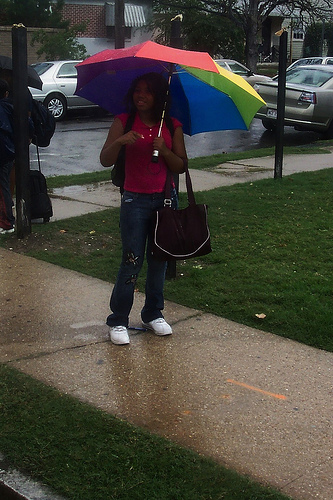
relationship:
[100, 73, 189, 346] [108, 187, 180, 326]
girl wearing pants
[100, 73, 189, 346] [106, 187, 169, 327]
girl wearing blue jeans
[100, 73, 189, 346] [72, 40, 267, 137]
girl holding umbrella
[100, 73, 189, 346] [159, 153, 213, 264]
girl holding purse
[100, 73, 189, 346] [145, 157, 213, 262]
girl holding purse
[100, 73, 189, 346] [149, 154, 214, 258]
girl holding purse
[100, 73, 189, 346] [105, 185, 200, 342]
girl wearing pants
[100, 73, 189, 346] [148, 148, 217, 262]
girl holding purse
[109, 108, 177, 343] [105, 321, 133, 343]
girl wearing shoes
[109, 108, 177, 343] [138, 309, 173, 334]
girl wearing shoes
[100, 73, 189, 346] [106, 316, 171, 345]
girl wearing shoes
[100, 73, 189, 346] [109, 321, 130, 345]
girl wearing shoes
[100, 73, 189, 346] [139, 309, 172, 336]
girl wearing shoes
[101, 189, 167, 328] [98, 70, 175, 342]
blue jeans on girl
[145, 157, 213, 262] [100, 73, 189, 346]
purse on girl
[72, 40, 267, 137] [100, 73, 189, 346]
umbrella with girl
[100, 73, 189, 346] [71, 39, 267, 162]
girl with umbrella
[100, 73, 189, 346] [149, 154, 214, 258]
girl with purse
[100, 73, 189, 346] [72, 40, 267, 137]
girl with umbrella